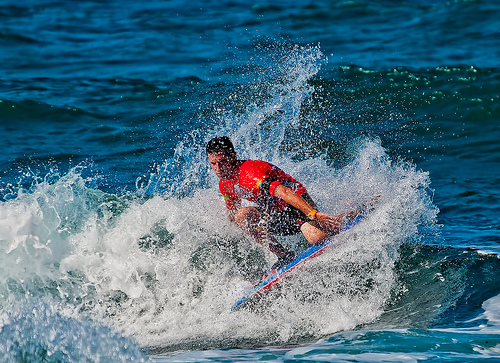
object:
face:
[208, 153, 236, 180]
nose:
[215, 161, 222, 171]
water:
[0, 12, 447, 361]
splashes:
[99, 222, 206, 307]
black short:
[256, 190, 318, 236]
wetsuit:
[215, 158, 320, 238]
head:
[206, 136, 237, 180]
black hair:
[206, 136, 236, 159]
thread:
[253, 216, 277, 281]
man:
[205, 136, 341, 274]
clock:
[307, 209, 318, 220]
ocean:
[0, 1, 498, 361]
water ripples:
[22, 60, 166, 121]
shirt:
[219, 160, 307, 210]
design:
[233, 182, 255, 199]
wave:
[27, 188, 262, 317]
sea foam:
[7, 39, 212, 299]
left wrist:
[306, 208, 321, 221]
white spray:
[175, 41, 329, 152]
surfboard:
[229, 203, 378, 313]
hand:
[313, 210, 343, 231]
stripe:
[260, 177, 278, 197]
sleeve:
[256, 174, 282, 198]